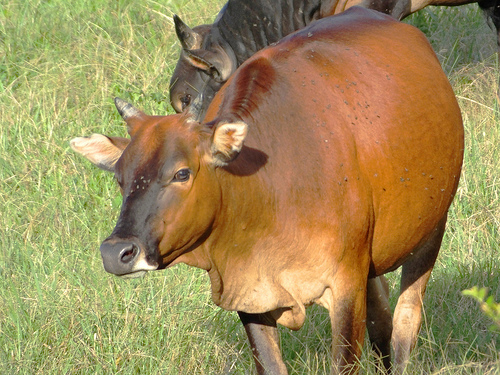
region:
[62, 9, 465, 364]
brown cow in a field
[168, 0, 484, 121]
black cow in a field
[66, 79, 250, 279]
the cow is looking to its left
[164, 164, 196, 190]
the cow's left eye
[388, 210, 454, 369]
the cow's left hind leg is slightly forward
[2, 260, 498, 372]
light green tall grass in the field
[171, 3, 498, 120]
the black cow is eating the grass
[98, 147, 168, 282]
cow has a dark brown nose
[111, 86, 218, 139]
horn stubs on the cow's head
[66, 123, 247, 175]
ears on the cow are pointing diagonally outward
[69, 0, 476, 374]
Cows in the grass.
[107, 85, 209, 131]
Horns on the cow.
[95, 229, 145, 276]
black nose on the cow.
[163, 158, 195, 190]
Brown eye on the cow.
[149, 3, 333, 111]
Black coloring on the animal.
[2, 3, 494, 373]
Grass covering the ground.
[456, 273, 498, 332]
plant in the grass.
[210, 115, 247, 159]
Tan coloring inside the ear.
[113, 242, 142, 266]
nostril on the nose.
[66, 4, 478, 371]
two cows are in a field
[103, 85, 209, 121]
the cow has two small horns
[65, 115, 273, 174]
the cows eats have hair in them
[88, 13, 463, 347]
the cow is a reddish brown color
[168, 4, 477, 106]
a cow is behind the brown cow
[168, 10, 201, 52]
the darker cow also has horns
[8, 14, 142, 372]
the grass is green and yellow in color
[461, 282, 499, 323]
a green leaf on the right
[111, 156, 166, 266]
the cow has a darker face than its body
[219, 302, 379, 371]
the cows front legs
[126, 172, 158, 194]
Flies at the nose of a carabao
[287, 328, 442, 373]
There are tall and thin grass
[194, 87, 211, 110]
The tip of a carabaos' black horn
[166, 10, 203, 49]
A short horn of a carabao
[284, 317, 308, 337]
Tip of the carabaos' loose skin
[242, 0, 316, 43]
A wrinkled carabao skin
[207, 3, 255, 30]
Top of the carabaos' black neck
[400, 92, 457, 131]
Smooth skin of a carabao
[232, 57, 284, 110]
The carabaos' brown back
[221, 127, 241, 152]
Brown hair inside the carabaos's ear